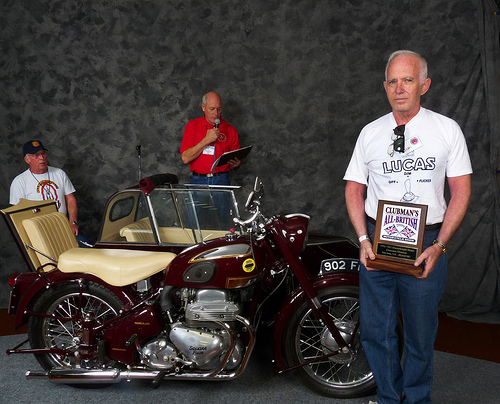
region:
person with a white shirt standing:
[333, 41, 480, 401]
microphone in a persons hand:
[211, 115, 223, 135]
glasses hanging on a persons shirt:
[387, 120, 409, 156]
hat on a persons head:
[18, 137, 51, 157]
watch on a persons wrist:
[430, 235, 452, 258]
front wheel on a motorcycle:
[280, 270, 406, 400]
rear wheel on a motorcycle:
[18, 275, 142, 393]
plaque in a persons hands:
[361, 194, 436, 286]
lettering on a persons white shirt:
[376, 151, 441, 177]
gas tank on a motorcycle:
[158, 226, 275, 296]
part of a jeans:
[357, 326, 374, 373]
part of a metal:
[221, 327, 245, 357]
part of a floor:
[256, 368, 266, 383]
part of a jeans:
[378, 346, 393, 378]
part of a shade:
[253, 357, 260, 372]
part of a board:
[378, 233, 426, 300]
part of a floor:
[450, 362, 490, 384]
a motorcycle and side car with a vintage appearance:
[5, 181, 372, 398]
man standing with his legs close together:
[343, 48, 472, 402]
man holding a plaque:
[357, 198, 442, 278]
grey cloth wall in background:
[1, 1, 497, 326]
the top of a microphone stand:
[133, 141, 143, 181]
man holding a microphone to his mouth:
[179, 90, 222, 165]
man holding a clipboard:
[210, 142, 253, 174]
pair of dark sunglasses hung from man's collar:
[393, 119, 408, 154]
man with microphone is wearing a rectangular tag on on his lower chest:
[180, 93, 223, 158]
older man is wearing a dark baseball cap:
[21, 140, 49, 174]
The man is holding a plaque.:
[371, 195, 447, 285]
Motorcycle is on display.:
[30, 180, 347, 370]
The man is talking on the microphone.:
[191, 77, 244, 174]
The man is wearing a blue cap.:
[9, 137, 66, 148]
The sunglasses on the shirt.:
[381, 118, 413, 149]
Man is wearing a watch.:
[348, 217, 393, 252]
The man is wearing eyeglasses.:
[29, 152, 56, 159]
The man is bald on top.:
[201, 81, 226, 103]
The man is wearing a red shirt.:
[181, 119, 260, 163]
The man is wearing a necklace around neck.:
[26, 168, 77, 193]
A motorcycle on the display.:
[51, 206, 346, 368]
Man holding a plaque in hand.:
[378, 196, 437, 271]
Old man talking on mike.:
[183, 82, 246, 191]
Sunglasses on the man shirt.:
[387, 110, 423, 158]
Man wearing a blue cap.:
[22, 137, 67, 153]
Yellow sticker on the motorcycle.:
[232, 245, 255, 278]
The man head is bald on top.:
[196, 77, 226, 100]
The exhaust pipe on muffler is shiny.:
[18, 360, 154, 386]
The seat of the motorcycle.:
[46, 235, 176, 282]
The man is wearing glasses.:
[23, 148, 56, 163]